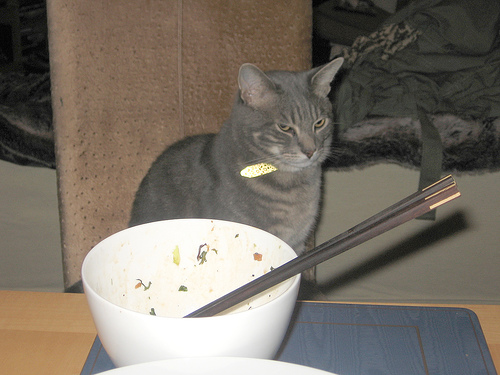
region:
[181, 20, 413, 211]
gray cat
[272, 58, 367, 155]
gray cat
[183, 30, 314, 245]
gray cat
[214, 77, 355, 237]
gray cat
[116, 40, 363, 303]
cat stares appraisingly @ abandoned dish of, yukk, salad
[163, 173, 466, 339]
salad seems to have been eaten w/ chopsticks & w/o cat's consultation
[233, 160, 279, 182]
cat has goldtone - golden - collar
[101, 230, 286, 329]
remnants of whatever was in the salad bowl the cat doesnt want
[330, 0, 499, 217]
somebody's laundry or somebody's jacket in the background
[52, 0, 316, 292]
cat's chair seems to be made of ostrich hide, i kid thee not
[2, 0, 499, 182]
a greyish woolly blanket beneath jacket/laundry & behind cat/ex-salad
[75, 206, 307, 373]
salad bowl is quite deep & round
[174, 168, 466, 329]
one chopstick is brown, the other black. they both have goldtone appointments @ their ends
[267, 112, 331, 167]
cat has golden eyes, greyish pink nose, someone else's unwanted old food & a table w/ a dark blue placemat [taffeta?] before it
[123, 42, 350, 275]
a grey cat sitting next to a bowl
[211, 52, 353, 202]
a grey cat wearing a gold collar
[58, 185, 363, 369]
a white bowl with chop sticks in it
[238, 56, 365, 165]
a grey cat with yellow eyes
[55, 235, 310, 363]
a dirty white bowl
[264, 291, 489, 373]
a blue place mat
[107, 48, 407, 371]
a cat sitting on a table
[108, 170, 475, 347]
a pair of chop sticks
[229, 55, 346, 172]
a grey cat with stripes on its head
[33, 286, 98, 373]
a wooden table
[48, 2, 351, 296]
Gray cat sitting on a chair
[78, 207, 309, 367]
Bowl for eating noodles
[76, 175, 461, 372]
Chopsticks resting in noodle bowl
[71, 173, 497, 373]
Noodle bowl and chopsticks resting on blue placemat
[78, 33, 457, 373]
Gray cat sitting behind noodle bowl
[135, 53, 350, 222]
Gray cat with gold collar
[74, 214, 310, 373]
White bowl dirty from use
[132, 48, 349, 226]
Cat with yellow eyes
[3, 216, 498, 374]
Dishes and placemat on dining table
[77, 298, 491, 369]
Blue placemat with brown detailing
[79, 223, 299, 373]
shallow white dining bowl